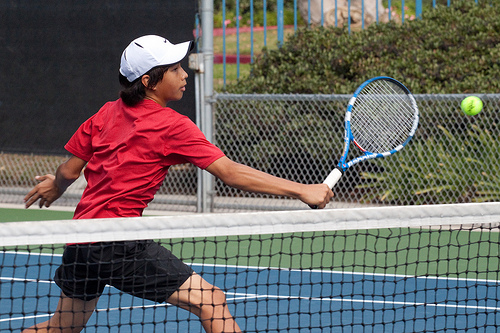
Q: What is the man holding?
A: A racket.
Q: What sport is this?
A: Tennis.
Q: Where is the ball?
A: In the air.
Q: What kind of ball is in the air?
A: Tennis ball.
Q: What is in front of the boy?
A: Net.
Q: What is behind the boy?
A: Fence.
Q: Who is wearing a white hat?
A: Tennis player.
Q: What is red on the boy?
A: Shirt.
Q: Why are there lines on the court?
A: Designated boundaries.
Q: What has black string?
A: Net across court.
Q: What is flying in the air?
A: Tennis ball.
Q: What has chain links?
A: Fence.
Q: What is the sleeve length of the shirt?
A: Short.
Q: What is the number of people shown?
A: One.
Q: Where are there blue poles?
A: Behind bush.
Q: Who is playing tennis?
A: An athlete.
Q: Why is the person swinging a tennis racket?
A: To hit a ball.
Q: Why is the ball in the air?
A: The tennis player hit it.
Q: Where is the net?
A: In front of the tennis player.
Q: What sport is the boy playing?
A: Tennis.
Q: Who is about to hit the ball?
A: The boy.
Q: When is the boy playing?
A: During the day.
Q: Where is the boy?
A: Near the net.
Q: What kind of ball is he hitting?
A: Tennis ball.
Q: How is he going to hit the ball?
A: With a backhand swing.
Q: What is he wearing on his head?
A: White cap.